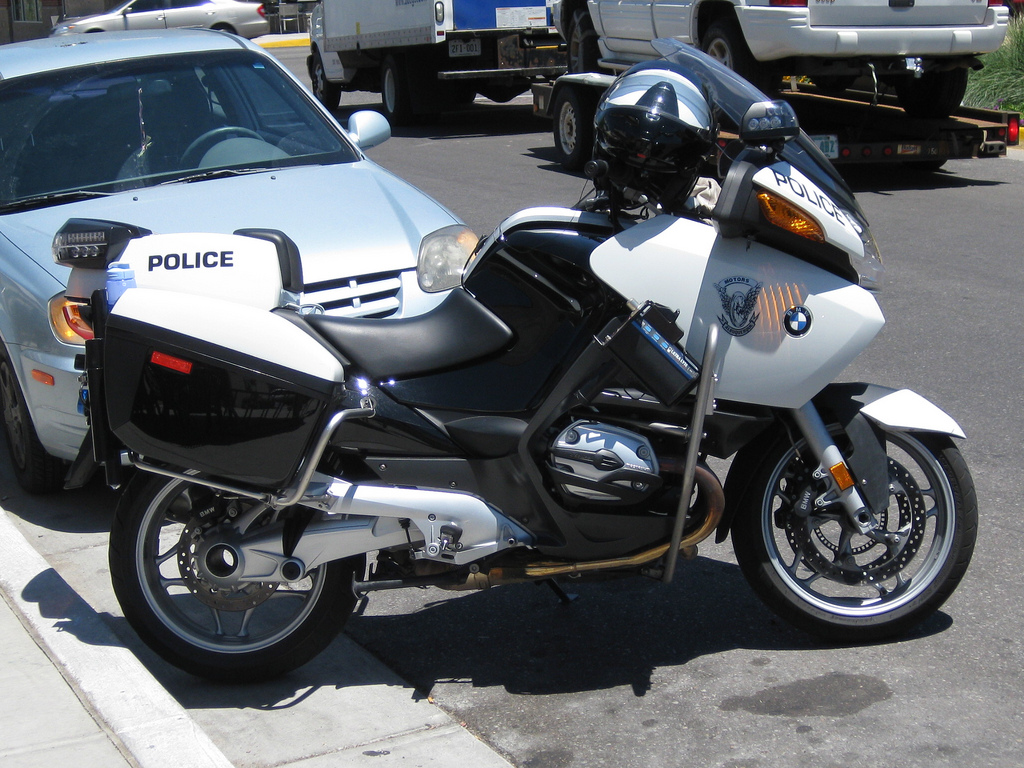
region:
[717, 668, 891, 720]
A wet stain on the road.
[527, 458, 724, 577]
A gold chrome bar.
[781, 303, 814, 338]
A small and rounded logo.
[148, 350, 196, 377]
A red and rectangular reflector light.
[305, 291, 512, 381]
A gray and leather seat.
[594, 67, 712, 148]
A white helmet with black design.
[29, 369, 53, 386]
A small and orange light.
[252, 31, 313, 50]
A stripe of white and yellow lines.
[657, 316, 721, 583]
A gray and small bar.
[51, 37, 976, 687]
The motorbike is white and black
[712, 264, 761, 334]
Police logo on the side of bike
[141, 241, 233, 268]
Black letters on the side of bike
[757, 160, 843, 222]
Black letters on the side of bike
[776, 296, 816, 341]
Logo on the side of bike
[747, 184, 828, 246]
Orange light on the bike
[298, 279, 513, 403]
Black seat on the bike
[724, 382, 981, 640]
Wheel of a motorbike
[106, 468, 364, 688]
Wheel of a motorbike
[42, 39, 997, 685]
motorcycle parked at curb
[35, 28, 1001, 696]
motorcycle is for police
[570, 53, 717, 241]
helmet is sitting on motorcycle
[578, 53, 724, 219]
helmet on motorcycle is silver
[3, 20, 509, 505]
small car beside curb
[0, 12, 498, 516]
small car is silver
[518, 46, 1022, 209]
trailer attached to truck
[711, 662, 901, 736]
puddle stain beside motorcycle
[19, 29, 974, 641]
Motorcycle parked on the curb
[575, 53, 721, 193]
Helmet on the bike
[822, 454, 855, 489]
Reflector on the bike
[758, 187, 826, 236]
Reflector on the bike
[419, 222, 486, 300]
Head light on the car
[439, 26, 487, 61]
License plate on the truck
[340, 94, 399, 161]
blue mirror on the car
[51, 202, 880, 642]
A police motorcycle in front of the car.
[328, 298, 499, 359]
The black seat on the motorcycle.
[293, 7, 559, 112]
A white truck on the road.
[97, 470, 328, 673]
The back wheel of the motorcycle.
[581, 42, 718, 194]
A helmet on top of the bike.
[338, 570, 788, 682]
Shadow on the ground.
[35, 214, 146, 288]
Black box on the back of the motorcycle.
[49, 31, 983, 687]
Motorcycle has bmw logo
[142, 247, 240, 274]
Word police on the motorcycle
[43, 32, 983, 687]
Motorcycle has leather seat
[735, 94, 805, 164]
Black side mirror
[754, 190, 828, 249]
Amber light in the front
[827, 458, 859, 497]
Small rectangular amber light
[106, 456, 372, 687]
Round black tire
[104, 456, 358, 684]
The wheel on a vehicle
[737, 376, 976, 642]
The wheel on a vehicle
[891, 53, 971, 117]
The wheel on a vehicle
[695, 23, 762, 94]
The wheel on a vehicle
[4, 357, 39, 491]
The wheel on a vehicle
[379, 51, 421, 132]
The wheel on a vehicle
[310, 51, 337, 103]
The wheel on a vehicle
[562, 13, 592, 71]
The wheel on a vehicle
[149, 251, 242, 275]
the text is black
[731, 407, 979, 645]
the tire is black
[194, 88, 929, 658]
this is a police motorcycle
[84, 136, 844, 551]
the motorcycle is white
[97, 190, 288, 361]
the text says POLICE